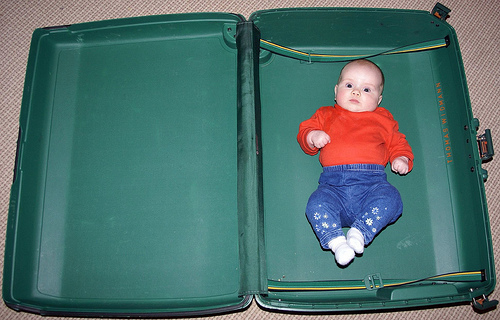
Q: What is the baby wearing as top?
A: Red shirt.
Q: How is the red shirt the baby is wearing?
A: Long-sleeved.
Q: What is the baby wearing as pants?
A: Blue jeans.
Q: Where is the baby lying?
A: In open green suitcase.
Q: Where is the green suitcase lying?
A: On beige rug.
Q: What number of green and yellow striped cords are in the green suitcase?
A: Two.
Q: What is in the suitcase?
A: A baby.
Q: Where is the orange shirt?
A: On the baby.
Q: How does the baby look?
A: Scared.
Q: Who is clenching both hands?
A: Baby.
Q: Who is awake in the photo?
A: Baby.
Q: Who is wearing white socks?
A: Baby.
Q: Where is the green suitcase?
A: Floor.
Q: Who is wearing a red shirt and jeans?
A: Baby.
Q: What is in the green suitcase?
A: Baby.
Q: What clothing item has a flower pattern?
A: Blue jeans.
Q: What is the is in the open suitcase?
A: Baby.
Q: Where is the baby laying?
A: Suitcase.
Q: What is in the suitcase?
A: Baby.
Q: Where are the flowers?
A: Pant legs.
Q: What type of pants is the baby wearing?
A: Jeans.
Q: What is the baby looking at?
A: Camera.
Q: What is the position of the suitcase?
A: Open.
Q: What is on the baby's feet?
A: Socks.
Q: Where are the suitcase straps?
A: Above and below the baby.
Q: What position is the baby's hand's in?
A: Fists.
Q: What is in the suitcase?
A: Baby.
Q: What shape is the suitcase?
A: Rectangle.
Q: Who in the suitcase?
A: The child.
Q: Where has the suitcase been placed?
A: On the bed.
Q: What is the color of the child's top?
A: Orange.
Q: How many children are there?
A: 1.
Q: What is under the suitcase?
A: Sheet.